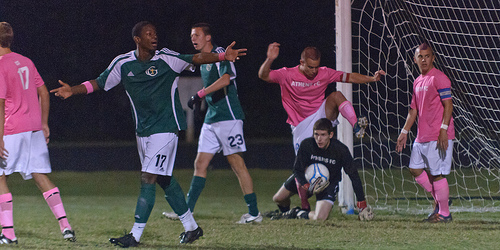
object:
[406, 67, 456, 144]
shirt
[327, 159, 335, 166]
letters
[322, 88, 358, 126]
leg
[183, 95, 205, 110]
black glove/man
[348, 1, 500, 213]
net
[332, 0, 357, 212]
post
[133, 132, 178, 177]
shorts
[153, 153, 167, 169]
17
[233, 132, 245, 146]
number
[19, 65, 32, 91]
number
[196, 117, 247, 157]
shorts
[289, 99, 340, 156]
shorts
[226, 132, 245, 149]
number 23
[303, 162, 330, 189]
ball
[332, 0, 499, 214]
goal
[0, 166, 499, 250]
field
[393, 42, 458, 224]
man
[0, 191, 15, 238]
man socks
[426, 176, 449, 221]
man socks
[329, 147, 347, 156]
black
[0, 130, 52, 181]
shorts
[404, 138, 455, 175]
shorts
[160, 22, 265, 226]
player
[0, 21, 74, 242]
player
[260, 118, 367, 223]
man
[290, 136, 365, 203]
shirt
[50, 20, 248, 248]
man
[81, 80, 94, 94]
armband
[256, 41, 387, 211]
man